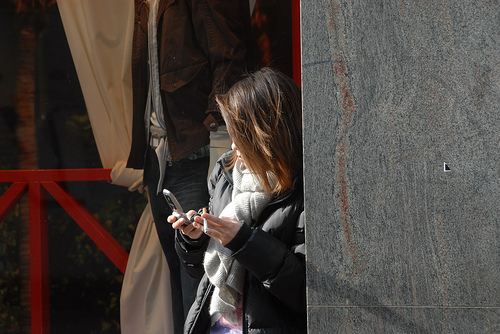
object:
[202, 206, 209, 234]
cigarette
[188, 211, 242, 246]
left hand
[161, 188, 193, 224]
cell phone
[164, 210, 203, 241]
right hand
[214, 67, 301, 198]
hair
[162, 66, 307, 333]
woman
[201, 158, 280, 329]
scarf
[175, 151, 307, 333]
coat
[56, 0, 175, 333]
cloth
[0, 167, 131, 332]
railing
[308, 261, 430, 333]
shadow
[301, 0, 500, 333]
wall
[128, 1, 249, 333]
person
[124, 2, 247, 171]
jacket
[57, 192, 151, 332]
bush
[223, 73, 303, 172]
head